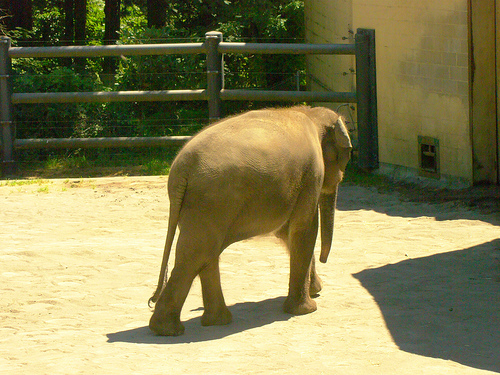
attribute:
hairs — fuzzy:
[169, 100, 320, 143]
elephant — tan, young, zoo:
[142, 101, 356, 341]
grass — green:
[337, 155, 397, 195]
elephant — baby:
[86, 55, 431, 372]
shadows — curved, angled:
[336, 187, 499, 364]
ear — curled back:
[330, 115, 350, 147]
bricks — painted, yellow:
[380, 26, 472, 173]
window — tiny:
[412, 136, 443, 173]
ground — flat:
[16, 175, 147, 351]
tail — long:
[152, 171, 192, 304]